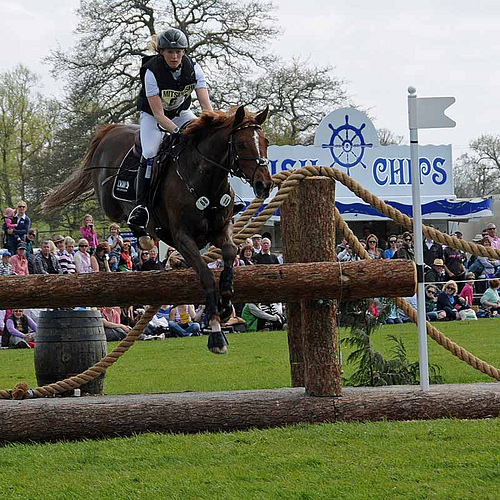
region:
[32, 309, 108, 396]
A brown wood barrel.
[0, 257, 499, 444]
Two brown wood poles.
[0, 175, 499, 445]
Four brown wood poles.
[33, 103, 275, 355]
A brown and white horse.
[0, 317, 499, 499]
Green grass on the ground.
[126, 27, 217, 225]
A girl on a horse.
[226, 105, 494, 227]
A blue and white sign.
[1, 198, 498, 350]
A crowd of people.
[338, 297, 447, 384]
A small green bush.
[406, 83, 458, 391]
A tall, white flag pole.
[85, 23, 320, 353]
Person riding a horse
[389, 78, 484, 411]
White plastic flag on a metal pole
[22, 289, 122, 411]
Wooden barrel with metal bands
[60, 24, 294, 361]
Horse jumping over a fence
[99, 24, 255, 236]
Woman wearing a black vest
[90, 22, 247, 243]
Woman wearing a helmet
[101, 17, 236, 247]
Woman wearing black boots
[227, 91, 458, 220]
White sign with blue writing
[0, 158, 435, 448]
Fence made of wooden logs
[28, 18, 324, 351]
Woman and horse jumping over a fence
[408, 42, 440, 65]
section of white clouds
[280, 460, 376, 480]
part of green grass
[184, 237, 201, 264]
front leg of a horse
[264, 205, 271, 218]
section of a rope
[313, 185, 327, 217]
section of a log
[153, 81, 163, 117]
left arm of a horse rider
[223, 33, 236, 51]
branches of a tree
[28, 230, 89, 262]
section of spectators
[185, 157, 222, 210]
part of a horses body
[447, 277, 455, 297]
a lady in the fans section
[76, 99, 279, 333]
brown horse jumping fence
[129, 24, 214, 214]
rider sitting on horse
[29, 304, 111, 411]
brown barrel behind fence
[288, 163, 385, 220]
thick brown rope on fence post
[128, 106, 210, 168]
white pants on rider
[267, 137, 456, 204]
blue and white sign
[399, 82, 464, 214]
white wooden flag on pole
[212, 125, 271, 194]
bridle on horse face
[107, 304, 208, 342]
spectators sitting on the ground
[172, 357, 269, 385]
neatly cut green grass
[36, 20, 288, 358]
a man on a horse jumping over a wooden fence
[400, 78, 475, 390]
a metal pole with a white metal flag at the top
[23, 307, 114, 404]
an old brown whiskey barrel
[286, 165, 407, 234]
some thick brown rope draped over a wooden pole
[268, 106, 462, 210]
a sign in the background that is white with blue lettering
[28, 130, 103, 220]
the long wispy tail of the horse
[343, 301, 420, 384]
a small green plant next to the flag pole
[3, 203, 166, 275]
a large crowd of people watching the event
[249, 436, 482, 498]
very bright green grass at the event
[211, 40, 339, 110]
tall bare trees in the background